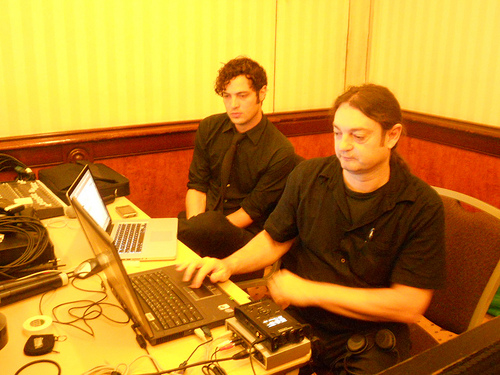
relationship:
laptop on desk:
[55, 185, 247, 348] [2, 198, 323, 372]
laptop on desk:
[53, 160, 183, 269] [2, 198, 323, 372]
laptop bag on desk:
[30, 145, 137, 208] [8, 176, 333, 372]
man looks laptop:
[176, 85, 446, 375] [55, 185, 247, 348]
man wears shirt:
[176, 85, 446, 375] [259, 149, 449, 323]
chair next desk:
[437, 185, 498, 357] [8, 176, 333, 372]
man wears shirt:
[179, 49, 307, 270] [181, 113, 299, 220]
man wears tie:
[179, 49, 306, 241] [217, 124, 246, 214]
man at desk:
[179, 49, 307, 270] [8, 176, 333, 372]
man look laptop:
[176, 85, 446, 375] [65, 193, 248, 344]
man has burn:
[179, 49, 307, 270] [250, 96, 262, 108]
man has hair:
[262, 69, 456, 370] [330, 78, 404, 125]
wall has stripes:
[10, 4, 499, 111] [2, 16, 494, 105]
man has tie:
[179, 49, 307, 270] [212, 124, 237, 205]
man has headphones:
[262, 69, 456, 370] [335, 320, 407, 363]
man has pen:
[176, 85, 446, 375] [362, 224, 374, 238]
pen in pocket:
[362, 224, 374, 238] [348, 242, 386, 272]